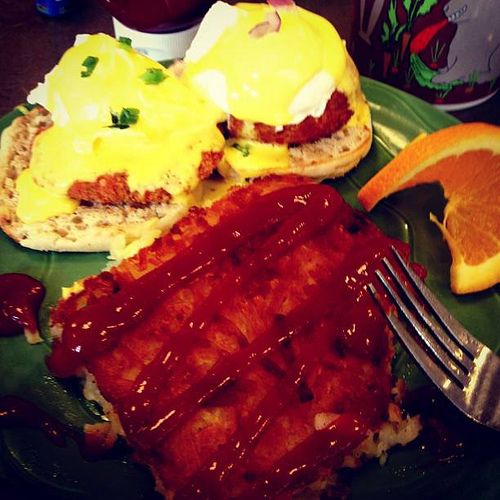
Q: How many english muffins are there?
A: Two.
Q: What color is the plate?
A: Green.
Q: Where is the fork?
A: On the right side of plate.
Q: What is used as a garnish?
A: An orange slice.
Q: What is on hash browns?
A: Ketchup.